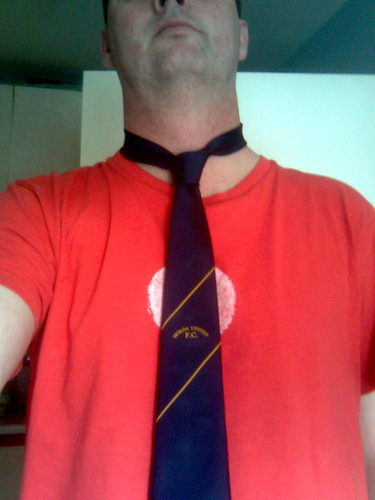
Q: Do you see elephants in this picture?
A: No, there are no elephants.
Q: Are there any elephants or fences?
A: No, there are no elephants or fences.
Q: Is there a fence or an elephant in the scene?
A: No, there are no elephants or fences.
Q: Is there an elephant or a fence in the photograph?
A: No, there are no elephants or fences.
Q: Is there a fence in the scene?
A: No, there are no fences.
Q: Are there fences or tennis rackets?
A: No, there are no fences or tennis rackets.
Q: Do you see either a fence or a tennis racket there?
A: No, there are no fences or rackets.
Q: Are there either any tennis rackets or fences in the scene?
A: No, there are no fences or tennis rackets.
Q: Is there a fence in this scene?
A: No, there are no fences.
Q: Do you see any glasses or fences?
A: No, there are no fences or glasses.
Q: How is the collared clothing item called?
A: The clothing item is a shirt.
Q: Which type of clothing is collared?
A: The clothing is a shirt.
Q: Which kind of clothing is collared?
A: The clothing is a shirt.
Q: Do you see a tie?
A: Yes, there is a tie.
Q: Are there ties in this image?
A: Yes, there is a tie.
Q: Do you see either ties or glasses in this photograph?
A: Yes, there is a tie.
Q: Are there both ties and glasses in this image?
A: No, there is a tie but no glasses.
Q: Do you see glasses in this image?
A: No, there are no glasses.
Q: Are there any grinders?
A: No, there are no grinders.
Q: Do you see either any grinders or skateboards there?
A: No, there are no grinders or skateboards.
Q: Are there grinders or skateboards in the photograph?
A: No, there are no grinders or skateboards.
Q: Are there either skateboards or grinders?
A: No, there are no grinders or skateboards.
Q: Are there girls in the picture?
A: No, there are no girls.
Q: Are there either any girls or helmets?
A: No, there are no girls or helmets.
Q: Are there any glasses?
A: No, there are no glasses.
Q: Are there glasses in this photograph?
A: No, there are no glasses.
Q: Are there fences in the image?
A: No, there are no fences.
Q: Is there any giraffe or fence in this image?
A: No, there are no fences or giraffes.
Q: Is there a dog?
A: No, there are no dogs.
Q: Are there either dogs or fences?
A: No, there are no dogs or fences.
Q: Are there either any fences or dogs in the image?
A: No, there are no dogs or fences.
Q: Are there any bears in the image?
A: No, there are no bears.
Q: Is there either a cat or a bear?
A: No, there are no bears or cats.